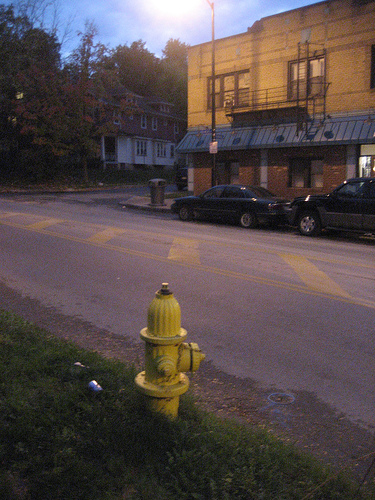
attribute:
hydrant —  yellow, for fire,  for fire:
[126, 275, 207, 425]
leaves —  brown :
[40, 313, 369, 477]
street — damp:
[0, 193, 373, 494]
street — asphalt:
[13, 214, 371, 400]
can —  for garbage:
[146, 178, 166, 210]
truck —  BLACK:
[279, 161, 373, 247]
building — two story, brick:
[182, 1, 372, 206]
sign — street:
[196, 130, 222, 157]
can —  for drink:
[83, 377, 116, 402]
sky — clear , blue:
[121, 14, 153, 27]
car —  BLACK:
[167, 176, 292, 230]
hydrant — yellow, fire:
[133, 281, 205, 422]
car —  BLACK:
[170, 178, 299, 231]